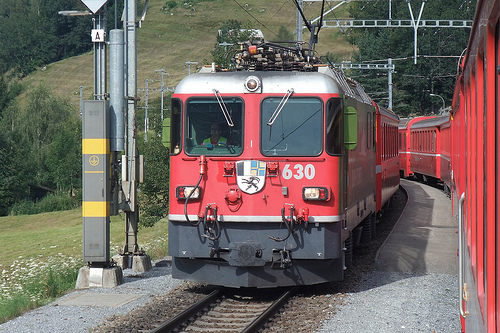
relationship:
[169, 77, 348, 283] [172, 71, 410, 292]
front of train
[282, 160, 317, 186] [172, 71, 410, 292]
630 on train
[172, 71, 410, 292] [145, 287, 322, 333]
train on tracks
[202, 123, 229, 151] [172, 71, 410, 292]
driver in train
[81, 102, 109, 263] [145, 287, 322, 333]
box next to tracks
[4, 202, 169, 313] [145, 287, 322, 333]
grass next to tracks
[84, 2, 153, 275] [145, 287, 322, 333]
poles next to tracks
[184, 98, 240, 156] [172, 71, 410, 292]
window on train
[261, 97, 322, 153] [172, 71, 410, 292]
window on train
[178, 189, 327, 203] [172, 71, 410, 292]
lights on train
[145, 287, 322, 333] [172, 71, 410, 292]
tracks in front of train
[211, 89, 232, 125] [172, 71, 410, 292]
windshield wiper on train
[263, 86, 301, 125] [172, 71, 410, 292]
windshield wiper on train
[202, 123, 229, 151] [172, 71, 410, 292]
driver in a train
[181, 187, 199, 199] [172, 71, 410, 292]
headlight on train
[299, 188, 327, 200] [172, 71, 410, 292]
headlight on train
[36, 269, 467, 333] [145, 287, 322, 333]
gravel along tracks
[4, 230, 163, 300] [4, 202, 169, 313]
flowers on edge of grass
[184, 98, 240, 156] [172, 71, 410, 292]
window on front of train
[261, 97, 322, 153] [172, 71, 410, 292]
window on front of train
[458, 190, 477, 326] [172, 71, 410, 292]
hand rail on side of train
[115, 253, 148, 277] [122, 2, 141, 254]
base of support beam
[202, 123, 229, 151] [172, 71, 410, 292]
driver driving train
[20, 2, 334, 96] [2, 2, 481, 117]
grass in background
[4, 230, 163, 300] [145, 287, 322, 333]
flowers beside tracks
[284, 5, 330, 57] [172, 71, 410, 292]
cable on top of train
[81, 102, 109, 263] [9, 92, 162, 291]
box on side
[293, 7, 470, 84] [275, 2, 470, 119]
rods are on top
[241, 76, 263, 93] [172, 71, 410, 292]
light indicator on train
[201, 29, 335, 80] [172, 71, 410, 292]
stuff on top of train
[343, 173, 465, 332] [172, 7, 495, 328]
pavement between trains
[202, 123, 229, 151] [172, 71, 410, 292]
driver inside train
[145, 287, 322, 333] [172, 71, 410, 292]
tracks of train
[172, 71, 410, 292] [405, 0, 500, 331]
train beside train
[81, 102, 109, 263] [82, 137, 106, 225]
box has stripes